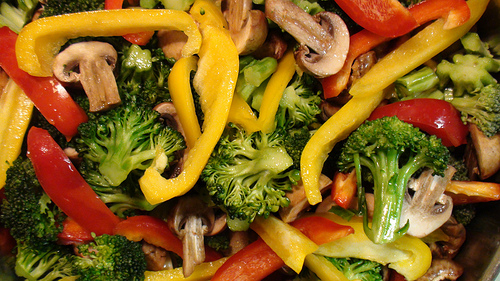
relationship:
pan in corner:
[450, 230, 488, 277] [431, 179, 492, 274]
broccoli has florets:
[212, 124, 338, 203] [221, 189, 289, 218]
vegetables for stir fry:
[84, 59, 499, 263] [171, 49, 367, 127]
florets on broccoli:
[221, 189, 289, 218] [212, 124, 338, 203]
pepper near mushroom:
[379, 107, 473, 148] [266, 0, 360, 74]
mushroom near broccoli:
[266, 0, 360, 74] [212, 124, 338, 203]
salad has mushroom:
[18, 36, 453, 263] [266, 0, 360, 74]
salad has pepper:
[18, 36, 453, 263] [379, 107, 473, 148]